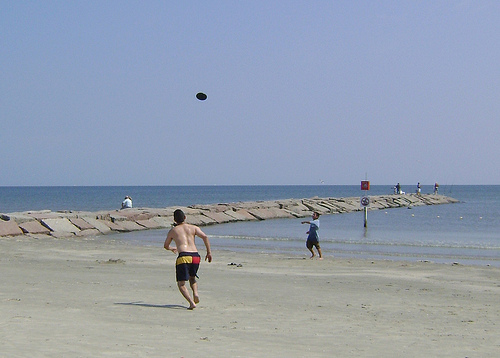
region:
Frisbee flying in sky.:
[186, 81, 226, 125]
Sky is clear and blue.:
[62, 58, 186, 113]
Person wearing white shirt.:
[118, 195, 135, 207]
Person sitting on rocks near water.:
[108, 193, 148, 219]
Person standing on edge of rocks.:
[408, 180, 430, 205]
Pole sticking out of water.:
[351, 170, 377, 251]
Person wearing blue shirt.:
[302, 218, 329, 233]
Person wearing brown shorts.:
[294, 236, 331, 256]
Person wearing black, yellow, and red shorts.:
[170, 253, 218, 286]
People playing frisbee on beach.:
[133, 233, 379, 288]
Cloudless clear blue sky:
[1, 1, 499, 186]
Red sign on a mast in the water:
[354, 175, 375, 231]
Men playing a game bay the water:
[158, 85, 331, 315]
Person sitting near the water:
[118, 194, 135, 211]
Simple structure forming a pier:
[0, 179, 460, 247]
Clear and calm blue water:
[1, 185, 499, 252]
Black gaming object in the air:
[191, 87, 211, 104]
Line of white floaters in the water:
[380, 205, 499, 227]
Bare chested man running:
[157, 205, 218, 313]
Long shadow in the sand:
[103, 278, 199, 315]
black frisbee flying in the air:
[194, 90, 207, 104]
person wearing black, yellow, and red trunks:
[163, 209, 212, 312]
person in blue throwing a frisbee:
[301, 209, 323, 261]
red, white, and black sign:
[358, 196, 369, 208]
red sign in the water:
[358, 181, 370, 191]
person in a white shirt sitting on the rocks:
[118, 194, 133, 209]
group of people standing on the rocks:
[388, 179, 442, 196]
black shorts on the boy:
[173, 251, 202, 283]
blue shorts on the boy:
[306, 218, 320, 235]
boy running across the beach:
[158, 205, 210, 315]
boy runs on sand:
[167, 209, 209, 320]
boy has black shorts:
[169, 239, 227, 290]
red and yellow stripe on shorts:
[165, 250, 226, 315]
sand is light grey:
[218, 291, 300, 356]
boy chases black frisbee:
[163, 43, 243, 350]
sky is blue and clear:
[240, 52, 385, 134]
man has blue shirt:
[306, 195, 322, 235]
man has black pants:
[305, 236, 326, 243]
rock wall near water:
[8, 184, 360, 236]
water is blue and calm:
[340, 211, 499, 258]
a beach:
[16, 206, 493, 344]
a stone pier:
[16, 169, 458, 236]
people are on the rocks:
[103, 175, 462, 219]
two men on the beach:
[159, 206, 335, 314]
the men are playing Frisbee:
[147, 78, 327, 305]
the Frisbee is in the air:
[183, 90, 217, 105]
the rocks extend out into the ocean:
[13, 162, 498, 268]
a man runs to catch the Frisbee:
[160, 205, 228, 312]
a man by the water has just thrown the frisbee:
[296, 206, 338, 261]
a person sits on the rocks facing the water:
[116, 192, 138, 214]